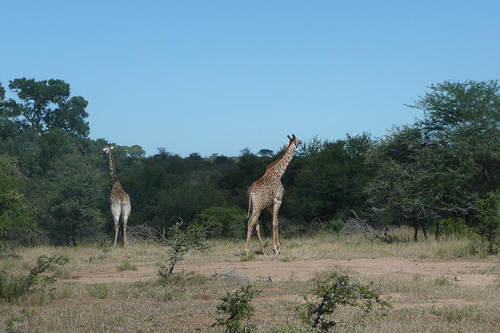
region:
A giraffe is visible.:
[230, 136, 274, 203]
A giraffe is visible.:
[195, 97, 328, 253]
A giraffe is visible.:
[205, 145, 270, 241]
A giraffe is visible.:
[211, 141, 343, 324]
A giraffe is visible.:
[230, 187, 290, 307]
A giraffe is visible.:
[251, 166, 323, 266]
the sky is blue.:
[0, 0, 495, 157]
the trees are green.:
[10, 80, 495, 242]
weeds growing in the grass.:
[209, 272, 374, 326]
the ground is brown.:
[12, 235, 493, 330]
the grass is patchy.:
[7, 235, 493, 329]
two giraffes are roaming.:
[77, 125, 312, 256]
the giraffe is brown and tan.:
[235, 122, 304, 258]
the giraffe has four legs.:
[237, 130, 306, 260]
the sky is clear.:
[2, 2, 499, 147]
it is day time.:
[2, 1, 497, 329]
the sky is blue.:
[206, 21, 280, 89]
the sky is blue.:
[178, 31, 293, 150]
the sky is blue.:
[144, 21, 261, 125]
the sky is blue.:
[179, 51, 433, 258]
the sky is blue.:
[146, 39, 200, 120]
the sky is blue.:
[119, 26, 214, 80]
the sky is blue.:
[168, 81, 188, 99]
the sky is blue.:
[146, 1, 233, 86]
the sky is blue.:
[213, 100, 298, 133]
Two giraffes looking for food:
[92, 124, 324, 272]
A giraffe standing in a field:
[55, 118, 178, 280]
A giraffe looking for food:
[216, 120, 338, 267]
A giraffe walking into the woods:
[225, 70, 491, 262]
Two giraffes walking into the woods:
[45, 103, 362, 284]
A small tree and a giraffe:
[74, 125, 213, 295]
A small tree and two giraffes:
[67, 117, 342, 278]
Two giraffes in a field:
[77, 127, 358, 267]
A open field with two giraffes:
[75, 112, 419, 331]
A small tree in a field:
[302, 112, 499, 328]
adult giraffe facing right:
[237, 132, 304, 262]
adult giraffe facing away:
[102, 139, 133, 254]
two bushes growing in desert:
[220, 270, 395, 332]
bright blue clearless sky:
[1, 4, 494, 151]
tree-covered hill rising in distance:
[125, 142, 357, 239]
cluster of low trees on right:
[368, 72, 497, 247]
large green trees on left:
[0, 71, 121, 251]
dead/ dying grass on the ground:
[49, 281, 205, 328]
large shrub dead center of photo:
[191, 205, 248, 239]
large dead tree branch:
[335, 201, 407, 251]